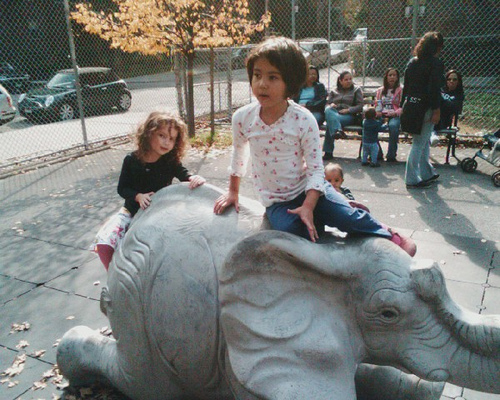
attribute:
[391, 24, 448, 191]
woman — standing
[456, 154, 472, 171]
ground — white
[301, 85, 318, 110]
shirt — blue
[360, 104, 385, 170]
toddler — small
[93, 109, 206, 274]
girl — climbing, young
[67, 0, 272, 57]
leaves — orange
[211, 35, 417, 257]
sister — older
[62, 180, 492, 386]
statue — elephant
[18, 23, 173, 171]
car — dark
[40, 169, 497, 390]
statue — elephant, grey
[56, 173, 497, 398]
elephant — stone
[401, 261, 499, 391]
trunk — up